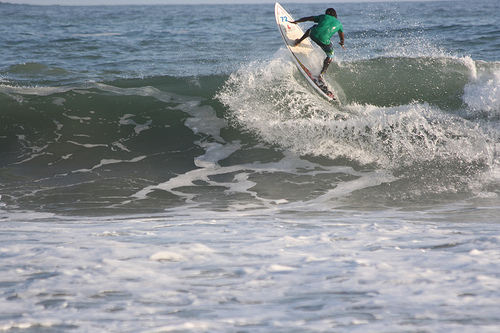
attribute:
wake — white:
[216, 47, 493, 161]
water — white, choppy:
[0, 212, 497, 330]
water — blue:
[1, 3, 496, 83]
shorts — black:
[308, 26, 334, 57]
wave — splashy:
[0, 56, 498, 205]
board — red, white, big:
[272, 2, 341, 104]